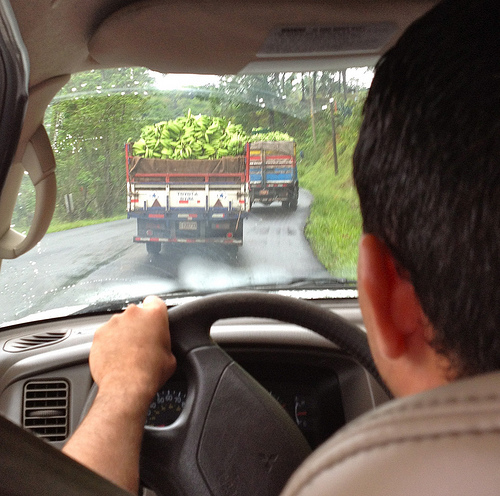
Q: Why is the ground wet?
A: It rained.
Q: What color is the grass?
A: Green.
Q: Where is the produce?
A: In the rear of the trucks.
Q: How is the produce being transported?
A: In the trucks.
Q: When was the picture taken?
A: Day time.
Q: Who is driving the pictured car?
A: A man.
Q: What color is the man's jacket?
A: Tan.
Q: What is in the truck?
A: Bananas.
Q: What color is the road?
A: Gray.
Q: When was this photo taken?
A: During the day.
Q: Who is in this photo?
A: A man driving.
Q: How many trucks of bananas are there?
A: Two.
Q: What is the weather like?
A: Rainy.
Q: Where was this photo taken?
A: Outside on the road.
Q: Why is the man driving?
A: He is traveling.